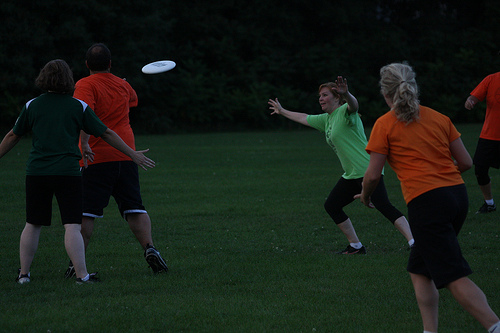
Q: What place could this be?
A: It is a park.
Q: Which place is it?
A: It is a park.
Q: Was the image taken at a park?
A: Yes, it was taken in a park.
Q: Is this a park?
A: Yes, it is a park.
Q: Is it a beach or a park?
A: It is a park.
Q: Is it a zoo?
A: No, it is a park.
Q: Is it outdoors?
A: Yes, it is outdoors.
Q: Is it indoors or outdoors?
A: It is outdoors.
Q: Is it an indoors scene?
A: No, it is outdoors.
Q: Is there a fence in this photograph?
A: No, there are no fences.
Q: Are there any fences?
A: No, there are no fences.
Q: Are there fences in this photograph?
A: No, there are no fences.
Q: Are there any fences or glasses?
A: No, there are no fences or glasses.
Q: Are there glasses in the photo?
A: No, there are no glasses.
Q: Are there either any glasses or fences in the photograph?
A: No, there are no glasses or fences.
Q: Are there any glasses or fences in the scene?
A: No, there are no glasses or fences.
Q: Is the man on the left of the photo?
A: Yes, the man is on the left of the image.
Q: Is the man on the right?
A: No, the man is on the left of the image.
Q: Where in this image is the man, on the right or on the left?
A: The man is on the left of the image.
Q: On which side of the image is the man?
A: The man is on the left of the image.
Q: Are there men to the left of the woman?
A: Yes, there is a man to the left of the woman.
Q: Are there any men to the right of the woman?
A: No, the man is to the left of the woman.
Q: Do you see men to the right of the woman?
A: No, the man is to the left of the woman.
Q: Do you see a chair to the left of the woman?
A: No, there is a man to the left of the woman.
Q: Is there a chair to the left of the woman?
A: No, there is a man to the left of the woman.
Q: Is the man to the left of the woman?
A: Yes, the man is to the left of the woman.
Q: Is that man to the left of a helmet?
A: No, the man is to the left of the woman.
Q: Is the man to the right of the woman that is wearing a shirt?
A: No, the man is to the left of the woman.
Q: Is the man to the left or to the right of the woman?
A: The man is to the left of the woman.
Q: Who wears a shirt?
A: The man wears a shirt.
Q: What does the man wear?
A: The man wears a shirt.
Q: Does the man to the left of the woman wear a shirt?
A: Yes, the man wears a shirt.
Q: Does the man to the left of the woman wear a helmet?
A: No, the man wears a shirt.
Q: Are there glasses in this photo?
A: No, there are no glasses.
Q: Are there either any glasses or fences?
A: No, there are no glasses or fences.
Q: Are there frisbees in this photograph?
A: Yes, there is a frisbee.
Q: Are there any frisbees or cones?
A: Yes, there is a frisbee.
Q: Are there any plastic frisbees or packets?
A: Yes, there is a plastic frisbee.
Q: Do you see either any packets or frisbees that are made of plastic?
A: Yes, the frisbee is made of plastic.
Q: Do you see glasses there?
A: No, there are no glasses.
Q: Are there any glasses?
A: No, there are no glasses.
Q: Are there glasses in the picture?
A: No, there are no glasses.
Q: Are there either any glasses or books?
A: No, there are no glasses or books.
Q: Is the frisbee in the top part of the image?
A: Yes, the frisbee is in the top of the image.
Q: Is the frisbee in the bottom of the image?
A: No, the frisbee is in the top of the image.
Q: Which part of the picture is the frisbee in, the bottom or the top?
A: The frisbee is in the top of the image.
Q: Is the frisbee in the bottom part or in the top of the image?
A: The frisbee is in the top of the image.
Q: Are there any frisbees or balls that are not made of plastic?
A: No, there is a frisbee but it is made of plastic.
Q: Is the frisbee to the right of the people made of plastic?
A: Yes, the frisbee is made of plastic.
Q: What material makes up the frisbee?
A: The frisbee is made of plastic.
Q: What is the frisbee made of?
A: The frisbee is made of plastic.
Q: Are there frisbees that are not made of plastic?
A: No, there is a frisbee but it is made of plastic.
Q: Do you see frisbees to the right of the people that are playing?
A: Yes, there is a frisbee to the right of the people.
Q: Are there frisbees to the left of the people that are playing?
A: No, the frisbee is to the right of the people.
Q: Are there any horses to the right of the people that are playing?
A: No, there is a frisbee to the right of the people.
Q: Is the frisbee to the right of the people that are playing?
A: Yes, the frisbee is to the right of the people.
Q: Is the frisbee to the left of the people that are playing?
A: No, the frisbee is to the right of the people.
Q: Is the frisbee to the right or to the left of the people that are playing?
A: The frisbee is to the right of the people.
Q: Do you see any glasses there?
A: No, there are no glasses.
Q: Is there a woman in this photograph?
A: Yes, there is a woman.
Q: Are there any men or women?
A: Yes, there is a woman.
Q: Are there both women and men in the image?
A: Yes, there are both a woman and a man.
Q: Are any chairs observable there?
A: No, there are no chairs.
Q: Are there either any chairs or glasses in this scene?
A: No, there are no chairs or glasses.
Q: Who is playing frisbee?
A: The woman is playing frisbee.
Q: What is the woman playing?
A: The woman is playing frisbee.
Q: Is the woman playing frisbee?
A: Yes, the woman is playing frisbee.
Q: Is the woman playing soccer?
A: No, the woman is playing frisbee.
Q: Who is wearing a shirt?
A: The woman is wearing a shirt.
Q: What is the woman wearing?
A: The woman is wearing a shirt.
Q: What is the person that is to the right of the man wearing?
A: The woman is wearing a shirt.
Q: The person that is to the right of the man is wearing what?
A: The woman is wearing a shirt.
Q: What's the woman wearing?
A: The woman is wearing a shirt.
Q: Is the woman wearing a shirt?
A: Yes, the woman is wearing a shirt.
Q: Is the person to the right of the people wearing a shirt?
A: Yes, the woman is wearing a shirt.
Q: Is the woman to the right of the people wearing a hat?
A: No, the woman is wearing a shirt.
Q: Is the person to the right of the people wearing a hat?
A: No, the woman is wearing a shirt.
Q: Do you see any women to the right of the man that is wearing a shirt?
A: Yes, there is a woman to the right of the man.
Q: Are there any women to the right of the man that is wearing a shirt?
A: Yes, there is a woman to the right of the man.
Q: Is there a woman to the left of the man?
A: No, the woman is to the right of the man.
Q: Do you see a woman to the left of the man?
A: No, the woman is to the right of the man.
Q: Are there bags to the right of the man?
A: No, there is a woman to the right of the man.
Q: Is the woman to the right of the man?
A: Yes, the woman is to the right of the man.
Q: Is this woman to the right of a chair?
A: No, the woman is to the right of the man.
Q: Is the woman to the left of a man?
A: No, the woman is to the right of a man.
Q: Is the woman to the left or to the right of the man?
A: The woman is to the right of the man.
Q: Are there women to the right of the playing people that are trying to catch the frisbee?
A: Yes, there is a woman to the right of the people.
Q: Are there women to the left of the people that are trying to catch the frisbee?
A: No, the woman is to the right of the people.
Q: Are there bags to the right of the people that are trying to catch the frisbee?
A: No, there is a woman to the right of the people.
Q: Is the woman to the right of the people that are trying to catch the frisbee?
A: Yes, the woman is to the right of the people.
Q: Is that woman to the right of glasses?
A: No, the woman is to the right of the people.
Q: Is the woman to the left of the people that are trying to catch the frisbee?
A: No, the woman is to the right of the people.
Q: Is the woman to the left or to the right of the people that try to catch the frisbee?
A: The woman is to the right of the people.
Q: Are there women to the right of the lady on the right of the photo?
A: No, the woman is to the left of the lady.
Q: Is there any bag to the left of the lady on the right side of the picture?
A: No, there is a woman to the left of the lady.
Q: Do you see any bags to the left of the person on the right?
A: No, there is a woman to the left of the lady.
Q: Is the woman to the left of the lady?
A: Yes, the woman is to the left of the lady.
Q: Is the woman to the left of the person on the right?
A: Yes, the woman is to the left of the lady.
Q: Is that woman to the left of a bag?
A: No, the woman is to the left of the lady.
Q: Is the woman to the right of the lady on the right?
A: No, the woman is to the left of the lady.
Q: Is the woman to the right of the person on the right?
A: No, the woman is to the left of the lady.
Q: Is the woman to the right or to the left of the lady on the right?
A: The woman is to the left of the lady.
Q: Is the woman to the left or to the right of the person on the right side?
A: The woman is to the left of the lady.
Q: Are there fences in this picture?
A: No, there are no fences.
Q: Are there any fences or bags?
A: No, there are no fences or bags.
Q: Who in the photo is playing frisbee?
A: The people are playing frisbee.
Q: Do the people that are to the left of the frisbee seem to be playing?
A: Yes, the people are playing.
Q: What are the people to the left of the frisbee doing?
A: The people are playing.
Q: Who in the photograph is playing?
A: The people are playing.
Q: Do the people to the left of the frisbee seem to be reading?
A: No, the people are playing.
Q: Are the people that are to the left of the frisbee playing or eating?
A: The people are playing.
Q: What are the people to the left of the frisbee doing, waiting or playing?
A: The people are playing.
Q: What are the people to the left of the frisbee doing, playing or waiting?
A: The people are playing.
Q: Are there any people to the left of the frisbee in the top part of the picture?
A: Yes, there are people to the left of the frisbee.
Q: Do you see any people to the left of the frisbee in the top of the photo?
A: Yes, there are people to the left of the frisbee.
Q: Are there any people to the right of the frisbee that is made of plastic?
A: No, the people are to the left of the frisbee.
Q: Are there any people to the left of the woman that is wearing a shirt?
A: Yes, there are people to the left of the woman.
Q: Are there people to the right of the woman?
A: No, the people are to the left of the woman.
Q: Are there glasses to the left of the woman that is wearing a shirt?
A: No, there are people to the left of the woman.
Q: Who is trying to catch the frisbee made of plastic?
A: The people are trying to catch the frisbee.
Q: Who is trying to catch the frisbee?
A: The people are trying to catch the frisbee.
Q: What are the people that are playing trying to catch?
A: The people are trying to catch the frisbee.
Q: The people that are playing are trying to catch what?
A: The people are trying to catch the frisbee.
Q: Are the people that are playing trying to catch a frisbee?
A: Yes, the people are trying to catch a frisbee.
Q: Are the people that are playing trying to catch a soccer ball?
A: No, the people are trying to catch a frisbee.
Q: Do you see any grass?
A: Yes, there is grass.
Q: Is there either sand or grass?
A: Yes, there is grass.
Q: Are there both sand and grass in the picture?
A: No, there is grass but no sand.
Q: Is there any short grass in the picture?
A: Yes, there is short grass.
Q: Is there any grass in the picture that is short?
A: Yes, there is grass that is short.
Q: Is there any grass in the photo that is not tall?
A: Yes, there is short grass.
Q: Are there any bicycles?
A: No, there are no bicycles.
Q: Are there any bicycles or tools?
A: No, there are no bicycles or tools.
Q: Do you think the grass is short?
A: Yes, the grass is short.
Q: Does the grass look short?
A: Yes, the grass is short.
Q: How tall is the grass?
A: The grass is short.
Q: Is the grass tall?
A: No, the grass is short.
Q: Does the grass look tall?
A: No, the grass is short.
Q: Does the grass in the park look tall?
A: No, the grass is short.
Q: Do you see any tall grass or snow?
A: No, there is grass but it is short.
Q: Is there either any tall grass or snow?
A: No, there is grass but it is short.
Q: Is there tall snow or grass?
A: No, there is grass but it is short.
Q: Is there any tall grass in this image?
A: No, there is grass but it is short.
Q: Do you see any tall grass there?
A: No, there is grass but it is short.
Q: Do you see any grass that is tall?
A: No, there is grass but it is short.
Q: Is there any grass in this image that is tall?
A: No, there is grass but it is short.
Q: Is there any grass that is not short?
A: No, there is grass but it is short.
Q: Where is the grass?
A: The grass is in the park.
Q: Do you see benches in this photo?
A: No, there are no benches.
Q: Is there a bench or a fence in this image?
A: No, there are no benches or fences.